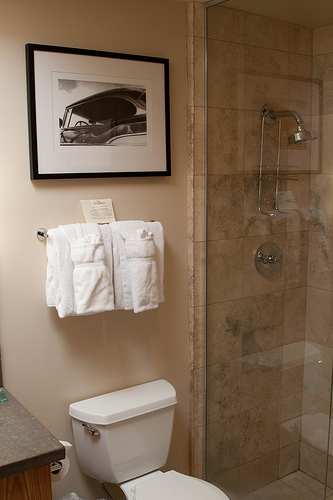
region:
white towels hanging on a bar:
[31, 221, 174, 324]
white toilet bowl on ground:
[68, 369, 231, 498]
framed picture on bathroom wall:
[16, 34, 180, 185]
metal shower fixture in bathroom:
[256, 97, 320, 148]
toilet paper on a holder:
[45, 435, 79, 484]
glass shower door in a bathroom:
[201, 1, 332, 499]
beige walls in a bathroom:
[18, 319, 189, 379]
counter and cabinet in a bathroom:
[2, 395, 70, 498]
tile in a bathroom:
[183, 303, 208, 371]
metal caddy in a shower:
[255, 104, 302, 224]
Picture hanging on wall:
[20, 33, 178, 181]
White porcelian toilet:
[66, 379, 212, 498]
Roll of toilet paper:
[50, 440, 78, 488]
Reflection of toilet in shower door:
[234, 343, 331, 460]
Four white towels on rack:
[40, 206, 172, 325]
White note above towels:
[77, 191, 132, 229]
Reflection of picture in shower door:
[230, 57, 328, 175]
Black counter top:
[2, 386, 73, 473]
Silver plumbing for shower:
[243, 96, 324, 285]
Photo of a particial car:
[53, 72, 151, 154]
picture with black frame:
[19, 36, 190, 192]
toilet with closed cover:
[153, 451, 229, 499]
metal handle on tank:
[76, 414, 103, 443]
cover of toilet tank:
[66, 373, 181, 434]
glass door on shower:
[214, 313, 303, 450]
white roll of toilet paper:
[43, 454, 75, 487]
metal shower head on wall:
[253, 94, 318, 163]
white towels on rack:
[27, 216, 177, 326]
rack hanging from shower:
[249, 109, 292, 227]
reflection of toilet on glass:
[235, 329, 328, 458]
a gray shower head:
[261, 105, 318, 149]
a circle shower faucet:
[254, 242, 285, 281]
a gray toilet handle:
[79, 423, 99, 438]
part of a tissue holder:
[47, 464, 61, 473]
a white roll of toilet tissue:
[47, 438, 72, 485]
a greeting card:
[78, 198, 117, 221]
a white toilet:
[68, 378, 234, 498]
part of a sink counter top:
[0, 391, 71, 476]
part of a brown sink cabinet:
[0, 462, 52, 498]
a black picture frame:
[20, 40, 174, 183]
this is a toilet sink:
[135, 470, 192, 490]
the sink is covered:
[151, 477, 220, 498]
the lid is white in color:
[161, 484, 201, 497]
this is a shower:
[279, 109, 318, 150]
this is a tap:
[260, 245, 286, 274]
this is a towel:
[70, 240, 144, 290]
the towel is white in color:
[60, 254, 81, 296]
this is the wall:
[21, 323, 75, 358]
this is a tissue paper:
[55, 464, 77, 484]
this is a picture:
[43, 59, 170, 178]